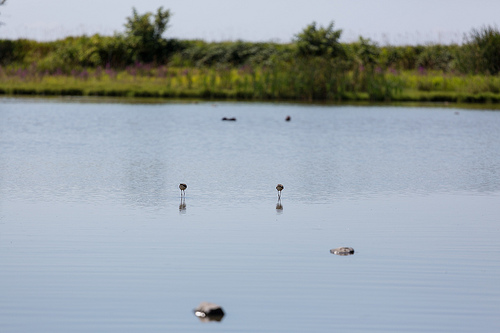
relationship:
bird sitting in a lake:
[179, 183, 187, 208] [0, 95, 499, 329]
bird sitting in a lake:
[275, 182, 284, 209] [0, 95, 499, 329]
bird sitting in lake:
[179, 183, 187, 208] [18, 113, 423, 298]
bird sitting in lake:
[275, 105, 315, 141] [17, 75, 493, 314]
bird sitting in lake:
[216, 109, 245, 129] [14, 69, 459, 318]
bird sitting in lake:
[180, 296, 253, 329] [14, 103, 461, 317]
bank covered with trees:
[10, 45, 453, 122] [276, 23, 357, 93]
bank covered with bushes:
[10, 45, 453, 122] [30, 5, 191, 69]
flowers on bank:
[19, 57, 184, 83] [10, 45, 453, 122]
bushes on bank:
[101, 20, 463, 71] [47, 31, 446, 127]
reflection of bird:
[176, 194, 294, 219] [275, 182, 284, 209]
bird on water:
[275, 182, 284, 209] [34, 93, 444, 282]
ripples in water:
[318, 153, 468, 194] [8, 82, 441, 285]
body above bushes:
[217, 13, 289, 45] [30, 28, 467, 140]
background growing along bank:
[0, 0, 500, 137] [10, 45, 453, 122]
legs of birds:
[167, 199, 300, 221] [176, 180, 290, 199]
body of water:
[365, 137, 457, 239] [34, 93, 444, 282]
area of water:
[24, 108, 147, 227] [24, 87, 467, 292]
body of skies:
[217, 13, 289, 45] [21, 11, 451, 75]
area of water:
[24, 108, 147, 227] [24, 83, 430, 273]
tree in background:
[118, 6, 170, 63] [39, 6, 470, 143]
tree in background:
[118, 6, 170, 63] [14, 11, 437, 137]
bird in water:
[179, 183, 187, 208] [121, 154, 277, 259]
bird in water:
[275, 182, 284, 209] [246, 166, 302, 220]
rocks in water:
[15, 83, 53, 99] [4, 92, 122, 161]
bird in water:
[179, 183, 187, 208] [1, 92, 499, 331]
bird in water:
[275, 182, 284, 209] [1, 92, 499, 331]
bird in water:
[274, 181, 284, 205] [1, 92, 499, 331]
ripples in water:
[318, 153, 468, 194] [1, 92, 499, 331]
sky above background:
[0, 0, 497, 44] [0, 0, 500, 137]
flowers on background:
[16, 65, 171, 75] [0, 0, 500, 137]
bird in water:
[191, 300, 227, 325] [1, 92, 499, 331]